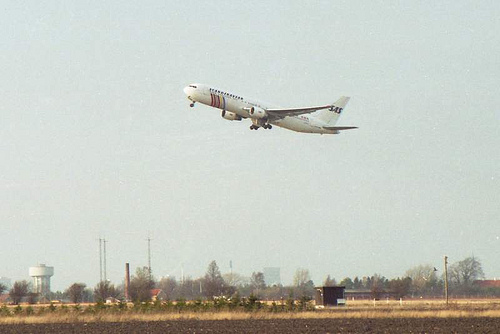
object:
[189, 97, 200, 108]
gear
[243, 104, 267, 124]
engine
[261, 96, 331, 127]
wing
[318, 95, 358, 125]
fin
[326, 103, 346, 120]
logo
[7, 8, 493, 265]
sky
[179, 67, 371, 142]
airplane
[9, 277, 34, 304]
tree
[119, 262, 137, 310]
stack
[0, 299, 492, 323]
field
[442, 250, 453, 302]
pole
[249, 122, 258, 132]
tire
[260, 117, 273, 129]
tire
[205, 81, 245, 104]
windows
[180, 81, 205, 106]
nose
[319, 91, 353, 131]
tail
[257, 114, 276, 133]
wheel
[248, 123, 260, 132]
wheel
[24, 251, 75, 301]
tower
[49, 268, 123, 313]
field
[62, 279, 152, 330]
trees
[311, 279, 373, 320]
building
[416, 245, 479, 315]
tree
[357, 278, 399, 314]
posts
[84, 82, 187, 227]
air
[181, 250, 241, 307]
tree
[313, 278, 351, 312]
building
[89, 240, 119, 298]
poles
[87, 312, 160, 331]
ground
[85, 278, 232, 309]
bushes